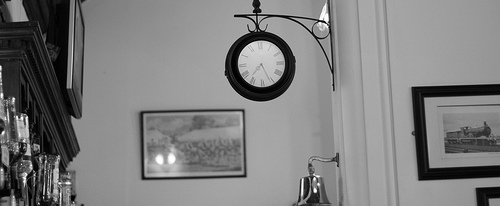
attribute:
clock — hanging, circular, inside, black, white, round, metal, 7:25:
[225, 26, 296, 101]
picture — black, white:
[140, 105, 247, 180]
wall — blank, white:
[67, 0, 336, 205]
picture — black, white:
[410, 84, 498, 181]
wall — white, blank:
[384, 0, 499, 205]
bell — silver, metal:
[292, 174, 333, 204]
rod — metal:
[232, 1, 337, 91]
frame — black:
[409, 84, 499, 178]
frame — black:
[473, 183, 499, 205]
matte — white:
[423, 94, 499, 167]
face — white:
[236, 39, 286, 86]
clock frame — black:
[224, 29, 296, 101]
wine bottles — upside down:
[1, 92, 37, 205]